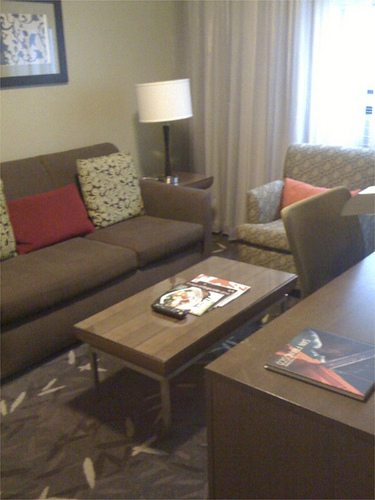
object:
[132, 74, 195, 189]
lamp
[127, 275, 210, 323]
book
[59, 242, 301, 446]
table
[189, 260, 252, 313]
books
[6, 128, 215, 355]
couch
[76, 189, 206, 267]
cushion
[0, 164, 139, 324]
cushion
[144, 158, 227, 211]
end table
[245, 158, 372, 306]
chair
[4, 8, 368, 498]
living room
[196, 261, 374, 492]
desk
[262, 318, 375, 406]
book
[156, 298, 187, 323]
remote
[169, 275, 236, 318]
magazines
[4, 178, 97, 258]
pillow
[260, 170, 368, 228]
pillow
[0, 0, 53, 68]
picture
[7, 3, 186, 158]
wall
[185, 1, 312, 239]
curtains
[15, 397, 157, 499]
carpet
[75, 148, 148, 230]
pillow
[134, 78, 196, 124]
shade